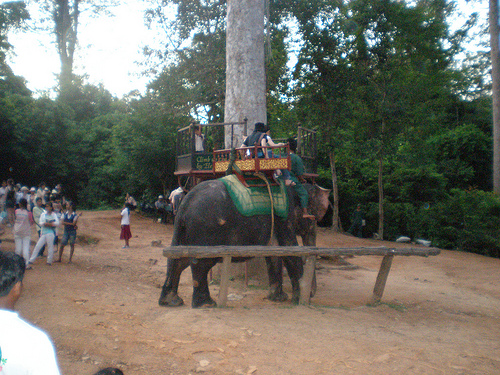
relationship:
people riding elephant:
[240, 120, 286, 156] [147, 157, 377, 304]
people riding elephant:
[242, 123, 284, 156] [163, 176, 325, 303]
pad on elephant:
[219, 173, 289, 223] [163, 176, 325, 303]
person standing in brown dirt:
[56, 199, 83, 264] [0, 208, 497, 374]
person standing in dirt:
[116, 191, 139, 263] [201, 310, 412, 367]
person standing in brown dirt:
[13, 196, 33, 270] [0, 208, 497, 374]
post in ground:
[158, 241, 443, 306] [283, 308, 360, 360]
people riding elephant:
[146, 102, 366, 239] [157, 174, 332, 309]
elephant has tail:
[177, 161, 300, 250] [163, 213, 180, 292]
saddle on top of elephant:
[212, 141, 292, 188] [157, 174, 332, 309]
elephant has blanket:
[157, 174, 332, 309] [213, 163, 294, 218]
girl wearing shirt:
[49, 205, 86, 266] [96, 193, 161, 277]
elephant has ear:
[157, 174, 332, 309] [313, 182, 329, 227]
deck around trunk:
[173, 118, 293, 191] [225, 0, 267, 144]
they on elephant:
[184, 121, 289, 158] [157, 174, 332, 309]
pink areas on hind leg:
[4, 206, 146, 296] [189, 253, 218, 312]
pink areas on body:
[4, 206, 146, 296] [197, 180, 276, 247]